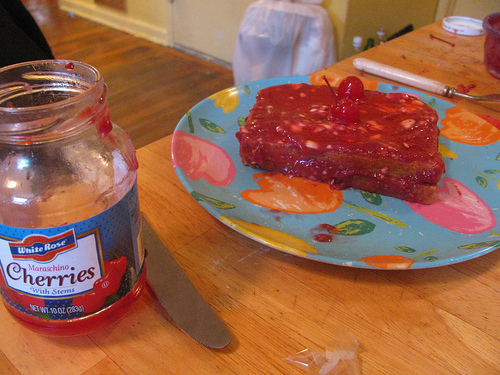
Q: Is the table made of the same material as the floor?
A: Yes, both the table and the floor are made of wood.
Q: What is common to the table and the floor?
A: The material, both the table and the floor are wooden.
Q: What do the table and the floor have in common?
A: The material, both the table and the floor are wooden.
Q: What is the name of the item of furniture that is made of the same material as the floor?
A: The piece of furniture is a table.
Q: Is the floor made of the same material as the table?
A: Yes, both the floor and the table are made of wood.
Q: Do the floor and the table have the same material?
A: Yes, both the floor and the table are made of wood.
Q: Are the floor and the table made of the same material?
A: Yes, both the floor and the table are made of wood.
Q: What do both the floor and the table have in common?
A: The material, both the floor and the table are wooden.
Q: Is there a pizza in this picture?
A: No, there are no pizzas.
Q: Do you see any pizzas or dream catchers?
A: No, there are no pizzas or dream catchers.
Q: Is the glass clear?
A: Yes, the glass is clear.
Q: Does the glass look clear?
A: Yes, the glass is clear.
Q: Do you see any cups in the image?
A: No, there are no cups.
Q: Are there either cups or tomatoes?
A: No, there are no cups or tomatoes.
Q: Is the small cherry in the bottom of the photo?
A: No, the cherry is in the top of the image.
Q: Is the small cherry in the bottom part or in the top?
A: The cherry is in the top of the image.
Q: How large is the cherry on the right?
A: The cherry is small.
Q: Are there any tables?
A: Yes, there is a table.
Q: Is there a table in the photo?
A: Yes, there is a table.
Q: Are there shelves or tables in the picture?
A: Yes, there is a table.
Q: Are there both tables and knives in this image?
A: Yes, there are both a table and a knife.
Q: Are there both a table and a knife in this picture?
A: Yes, there are both a table and a knife.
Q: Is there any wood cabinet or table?
A: Yes, there is a wood table.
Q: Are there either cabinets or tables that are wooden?
A: Yes, the table is wooden.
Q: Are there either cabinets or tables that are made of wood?
A: Yes, the table is made of wood.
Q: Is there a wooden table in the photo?
A: Yes, there is a wood table.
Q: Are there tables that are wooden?
A: Yes, there is a wood table.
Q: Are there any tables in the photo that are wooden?
A: Yes, there is a table that is wooden.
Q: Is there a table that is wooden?
A: Yes, there is a table that is wooden.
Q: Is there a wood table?
A: Yes, there is a table that is made of wood.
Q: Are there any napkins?
A: No, there are no napkins.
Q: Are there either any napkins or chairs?
A: No, there are no napkins or chairs.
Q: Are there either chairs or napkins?
A: No, there are no napkins or chairs.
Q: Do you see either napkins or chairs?
A: No, there are no napkins or chairs.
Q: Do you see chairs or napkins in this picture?
A: No, there are no napkins or chairs.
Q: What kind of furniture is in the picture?
A: The furniture is a table.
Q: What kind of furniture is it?
A: The piece of furniture is a table.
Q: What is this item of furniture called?
A: This is a table.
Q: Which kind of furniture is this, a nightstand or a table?
A: This is a table.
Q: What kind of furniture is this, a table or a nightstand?
A: This is a table.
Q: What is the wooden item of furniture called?
A: The piece of furniture is a table.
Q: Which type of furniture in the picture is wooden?
A: The furniture is a table.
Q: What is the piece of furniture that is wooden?
A: The piece of furniture is a table.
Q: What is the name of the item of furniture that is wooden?
A: The piece of furniture is a table.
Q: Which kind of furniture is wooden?
A: The furniture is a table.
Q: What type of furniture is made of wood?
A: The furniture is a table.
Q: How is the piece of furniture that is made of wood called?
A: The piece of furniture is a table.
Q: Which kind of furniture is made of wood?
A: The furniture is a table.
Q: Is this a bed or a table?
A: This is a table.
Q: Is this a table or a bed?
A: This is a table.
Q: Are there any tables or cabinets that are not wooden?
A: No, there is a table but it is wooden.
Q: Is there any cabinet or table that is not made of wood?
A: No, there is a table but it is made of wood.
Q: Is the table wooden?
A: Yes, the table is wooden.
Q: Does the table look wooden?
A: Yes, the table is wooden.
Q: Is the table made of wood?
A: Yes, the table is made of wood.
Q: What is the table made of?
A: The table is made of wood.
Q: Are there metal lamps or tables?
A: No, there is a table but it is wooden.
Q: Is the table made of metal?
A: No, the table is made of wood.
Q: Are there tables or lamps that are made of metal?
A: No, there is a table but it is made of wood.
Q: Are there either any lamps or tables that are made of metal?
A: No, there is a table but it is made of wood.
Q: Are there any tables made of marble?
A: No, there is a table but it is made of wood.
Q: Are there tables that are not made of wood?
A: No, there is a table but it is made of wood.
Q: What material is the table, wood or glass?
A: The table is made of wood.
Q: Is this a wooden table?
A: Yes, this is a wooden table.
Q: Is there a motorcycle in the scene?
A: No, there are no motorcycles.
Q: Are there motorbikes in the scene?
A: No, there are no motorbikes.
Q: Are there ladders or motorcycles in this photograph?
A: No, there are no motorcycles or ladders.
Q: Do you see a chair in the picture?
A: No, there are no chairs.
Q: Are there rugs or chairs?
A: No, there are no chairs or rugs.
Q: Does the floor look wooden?
A: Yes, the floor is wooden.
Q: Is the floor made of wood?
A: Yes, the floor is made of wood.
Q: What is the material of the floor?
A: The floor is made of wood.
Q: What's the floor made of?
A: The floor is made of wood.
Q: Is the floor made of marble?
A: No, the floor is made of wood.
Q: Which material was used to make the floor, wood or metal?
A: The floor is made of wood.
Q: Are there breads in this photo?
A: Yes, there is a bread.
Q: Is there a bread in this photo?
A: Yes, there is a bread.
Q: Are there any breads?
A: Yes, there is a bread.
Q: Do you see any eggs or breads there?
A: Yes, there is a bread.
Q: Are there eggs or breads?
A: Yes, there is a bread.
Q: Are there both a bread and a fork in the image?
A: Yes, there are both a bread and a fork.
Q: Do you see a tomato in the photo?
A: No, there are no tomatoes.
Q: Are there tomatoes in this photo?
A: No, there are no tomatoes.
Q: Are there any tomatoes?
A: No, there are no tomatoes.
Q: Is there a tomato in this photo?
A: No, there are no tomatoes.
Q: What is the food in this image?
A: The food is a bread.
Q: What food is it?
A: The food is a bread.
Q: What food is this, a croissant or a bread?
A: This is a bread.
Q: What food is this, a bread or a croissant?
A: This is a bread.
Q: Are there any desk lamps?
A: No, there are no desk lamps.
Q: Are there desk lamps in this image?
A: No, there are no desk lamps.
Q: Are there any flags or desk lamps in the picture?
A: No, there are no desk lamps or flags.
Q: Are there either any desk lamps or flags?
A: No, there are no desk lamps or flags.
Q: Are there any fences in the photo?
A: No, there are no fences.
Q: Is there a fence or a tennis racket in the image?
A: No, there are no fences or rackets.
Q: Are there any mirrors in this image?
A: No, there are no mirrors.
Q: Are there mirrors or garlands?
A: No, there are no mirrors or garlands.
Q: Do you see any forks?
A: Yes, there is a fork.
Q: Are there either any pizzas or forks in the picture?
A: Yes, there is a fork.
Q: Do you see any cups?
A: No, there are no cups.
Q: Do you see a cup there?
A: No, there are no cups.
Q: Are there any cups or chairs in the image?
A: No, there are no cups or chairs.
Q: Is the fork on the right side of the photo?
A: Yes, the fork is on the right of the image.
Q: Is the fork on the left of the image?
A: No, the fork is on the right of the image.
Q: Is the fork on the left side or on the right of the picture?
A: The fork is on the right of the image.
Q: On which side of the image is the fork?
A: The fork is on the right of the image.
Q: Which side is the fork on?
A: The fork is on the right of the image.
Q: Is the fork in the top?
A: Yes, the fork is in the top of the image.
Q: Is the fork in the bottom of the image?
A: No, the fork is in the top of the image.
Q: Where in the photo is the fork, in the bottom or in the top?
A: The fork is in the top of the image.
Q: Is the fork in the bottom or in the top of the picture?
A: The fork is in the top of the image.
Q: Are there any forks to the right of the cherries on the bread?
A: Yes, there is a fork to the right of the cherries.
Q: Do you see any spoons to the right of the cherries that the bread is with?
A: No, there is a fork to the right of the cherries.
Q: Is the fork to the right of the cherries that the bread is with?
A: Yes, the fork is to the right of the cherries.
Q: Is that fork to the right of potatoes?
A: No, the fork is to the right of the cherries.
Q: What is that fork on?
A: The fork is on the table.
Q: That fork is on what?
A: The fork is on the table.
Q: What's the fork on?
A: The fork is on the table.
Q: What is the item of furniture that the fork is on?
A: The piece of furniture is a table.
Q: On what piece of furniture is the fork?
A: The fork is on the table.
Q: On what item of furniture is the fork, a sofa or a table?
A: The fork is on a table.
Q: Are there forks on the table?
A: Yes, there is a fork on the table.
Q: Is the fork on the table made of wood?
A: Yes, the fork is on the table.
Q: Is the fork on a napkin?
A: No, the fork is on the table.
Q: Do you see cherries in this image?
A: Yes, there are cherries.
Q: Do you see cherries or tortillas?
A: Yes, there are cherries.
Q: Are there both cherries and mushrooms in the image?
A: No, there are cherries but no mushrooms.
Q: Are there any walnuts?
A: No, there are no walnuts.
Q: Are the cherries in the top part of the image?
A: Yes, the cherries are in the top of the image.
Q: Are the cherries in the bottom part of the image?
A: No, the cherries are in the top of the image.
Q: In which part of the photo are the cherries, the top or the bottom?
A: The cherries are in the top of the image.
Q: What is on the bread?
A: The cherries are on the bread.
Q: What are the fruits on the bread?
A: The fruits are cherries.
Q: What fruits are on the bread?
A: The fruits are cherries.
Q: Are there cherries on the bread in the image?
A: Yes, there are cherries on the bread.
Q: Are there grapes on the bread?
A: No, there are cherries on the bread.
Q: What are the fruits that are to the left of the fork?
A: The fruits are cherries.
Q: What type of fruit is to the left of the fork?
A: The fruits are cherries.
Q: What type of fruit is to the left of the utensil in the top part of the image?
A: The fruits are cherries.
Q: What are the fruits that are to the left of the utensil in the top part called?
A: The fruits are cherries.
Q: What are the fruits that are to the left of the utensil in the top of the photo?
A: The fruits are cherries.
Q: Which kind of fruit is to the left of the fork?
A: The fruits are cherries.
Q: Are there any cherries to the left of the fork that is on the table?
A: Yes, there are cherries to the left of the fork.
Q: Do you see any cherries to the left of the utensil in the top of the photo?
A: Yes, there are cherries to the left of the fork.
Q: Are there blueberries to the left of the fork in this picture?
A: No, there are cherries to the left of the fork.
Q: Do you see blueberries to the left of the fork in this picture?
A: No, there are cherries to the left of the fork.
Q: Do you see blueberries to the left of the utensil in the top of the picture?
A: No, there are cherries to the left of the fork.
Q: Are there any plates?
A: Yes, there is a plate.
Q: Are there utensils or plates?
A: Yes, there is a plate.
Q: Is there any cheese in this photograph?
A: No, there is no cheese.